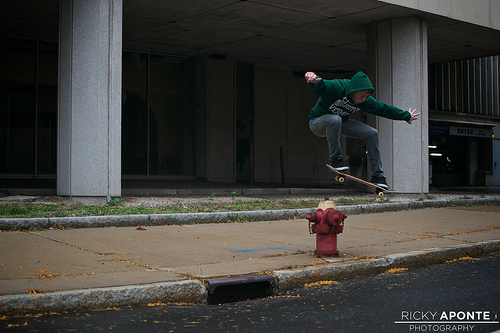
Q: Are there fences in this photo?
A: No, there are no fences.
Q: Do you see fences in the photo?
A: No, there are no fences.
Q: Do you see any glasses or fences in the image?
A: No, there are no fences or glasses.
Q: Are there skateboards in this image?
A: Yes, there is a skateboard.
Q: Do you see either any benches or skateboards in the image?
A: Yes, there is a skateboard.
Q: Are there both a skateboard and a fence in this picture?
A: No, there is a skateboard but no fences.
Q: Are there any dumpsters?
A: No, there are no dumpsters.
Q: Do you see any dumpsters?
A: No, there are no dumpsters.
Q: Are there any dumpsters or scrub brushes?
A: No, there are no dumpsters or scrub brushes.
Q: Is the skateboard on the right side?
A: Yes, the skateboard is on the right of the image.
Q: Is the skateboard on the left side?
A: No, the skateboard is on the right of the image.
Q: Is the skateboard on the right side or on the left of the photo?
A: The skateboard is on the right of the image.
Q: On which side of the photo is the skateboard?
A: The skateboard is on the right of the image.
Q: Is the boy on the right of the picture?
A: Yes, the boy is on the right of the image.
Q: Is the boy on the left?
A: No, the boy is on the right of the image.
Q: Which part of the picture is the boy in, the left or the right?
A: The boy is on the right of the image.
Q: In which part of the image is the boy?
A: The boy is on the right of the image.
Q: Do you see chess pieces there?
A: No, there are no chess pieces.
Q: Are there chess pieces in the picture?
A: No, there are no chess pieces.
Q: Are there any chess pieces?
A: No, there are no chess pieces.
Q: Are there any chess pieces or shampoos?
A: No, there are no chess pieces or shampoos.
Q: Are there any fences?
A: No, there are no fences.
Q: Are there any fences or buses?
A: No, there are no fences or buses.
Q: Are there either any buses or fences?
A: No, there are no fences or buses.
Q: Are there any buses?
A: No, there are no buses.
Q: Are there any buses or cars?
A: No, there are no buses or cars.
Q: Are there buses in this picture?
A: No, there are no buses.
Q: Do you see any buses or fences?
A: No, there are no buses or fences.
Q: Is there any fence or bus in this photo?
A: No, there are no buses or fences.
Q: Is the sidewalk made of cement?
A: Yes, the sidewalk is made of cement.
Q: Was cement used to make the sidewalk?
A: Yes, the sidewalk is made of cement.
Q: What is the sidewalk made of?
A: The sidewalk is made of concrete.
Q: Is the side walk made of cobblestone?
A: No, the side walk is made of concrete.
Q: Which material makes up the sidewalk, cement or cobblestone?
A: The sidewalk is made of cement.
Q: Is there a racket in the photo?
A: No, there are no rackets.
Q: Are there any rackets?
A: No, there are no rackets.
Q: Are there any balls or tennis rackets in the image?
A: No, there are no tennis rackets or balls.